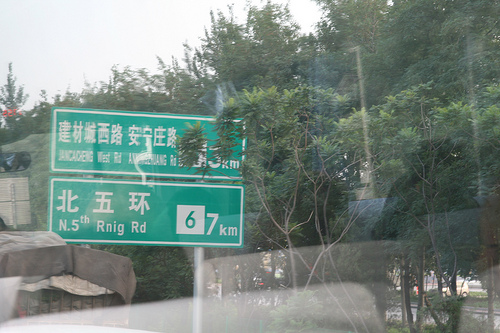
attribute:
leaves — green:
[309, 77, 496, 204]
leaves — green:
[175, 88, 361, 200]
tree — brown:
[316, 77, 498, 327]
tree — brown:
[175, 80, 383, 331]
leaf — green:
[270, 169, 276, 178]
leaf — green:
[311, 132, 318, 142]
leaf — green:
[323, 131, 328, 141]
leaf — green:
[299, 153, 309, 159]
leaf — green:
[259, 122, 268, 131]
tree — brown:
[168, 80, 418, 327]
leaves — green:
[416, 64, 454, 93]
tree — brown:
[378, 75, 492, 320]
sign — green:
[47, 111, 249, 176]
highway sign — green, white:
[53, 110, 251, 245]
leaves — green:
[345, 27, 495, 205]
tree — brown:
[357, 11, 464, 326]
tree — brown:
[368, 80, 495, 332]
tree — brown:
[175, 86, 360, 297]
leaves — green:
[243, 86, 281, 122]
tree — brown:
[271, 17, 499, 237]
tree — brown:
[369, 55, 446, 298]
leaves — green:
[391, 88, 475, 167]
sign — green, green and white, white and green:
[46, 102, 250, 184]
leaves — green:
[284, 8, 498, 128]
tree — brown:
[250, 113, 495, 330]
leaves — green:
[326, 93, 374, 141]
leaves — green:
[176, 86, 368, 194]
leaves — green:
[376, 5, 420, 41]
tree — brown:
[374, 5, 454, 62]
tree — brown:
[293, 0, 438, 99]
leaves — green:
[258, 67, 398, 175]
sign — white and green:
[45, 169, 245, 247]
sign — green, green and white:
[46, 177, 246, 252]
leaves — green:
[0, 0, 474, 281]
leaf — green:
[446, 100, 457, 113]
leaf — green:
[381, 90, 396, 102]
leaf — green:
[422, 78, 433, 91]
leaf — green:
[378, 106, 388, 117]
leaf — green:
[431, 112, 441, 120]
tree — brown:
[308, 176, 340, 286]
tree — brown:
[296, 77, 475, 250]